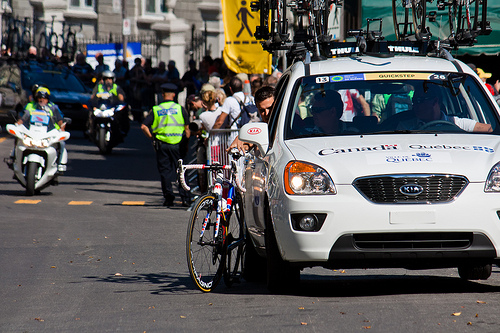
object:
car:
[235, 47, 497, 289]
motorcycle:
[4, 123, 72, 194]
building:
[0, 0, 224, 76]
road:
[0, 122, 500, 333]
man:
[142, 83, 192, 205]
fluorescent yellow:
[150, 101, 186, 146]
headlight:
[483, 160, 500, 195]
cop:
[90, 82, 126, 137]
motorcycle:
[90, 93, 129, 156]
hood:
[284, 133, 500, 182]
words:
[317, 144, 494, 164]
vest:
[150, 100, 185, 144]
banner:
[221, 1, 273, 76]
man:
[236, 1, 256, 38]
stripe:
[17, 197, 145, 207]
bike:
[179, 157, 244, 291]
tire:
[187, 194, 226, 293]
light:
[483, 161, 500, 192]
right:
[238, 4, 499, 331]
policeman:
[91, 70, 126, 110]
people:
[393, 88, 494, 135]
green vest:
[96, 82, 121, 99]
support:
[263, 40, 462, 63]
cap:
[160, 83, 179, 93]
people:
[195, 90, 232, 200]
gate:
[207, 129, 239, 198]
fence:
[205, 127, 249, 188]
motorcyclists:
[17, 88, 64, 134]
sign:
[88, 43, 141, 72]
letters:
[318, 143, 469, 156]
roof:
[250, 2, 489, 47]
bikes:
[253, 1, 492, 50]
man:
[305, 91, 355, 136]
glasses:
[311, 105, 336, 113]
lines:
[11, 197, 147, 205]